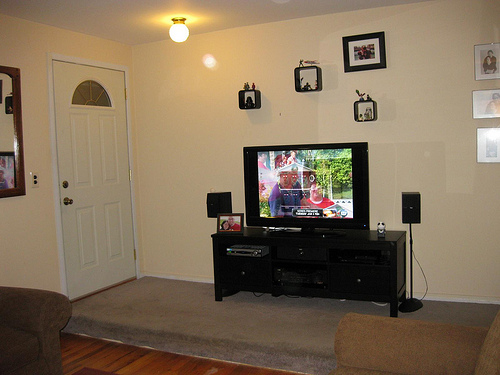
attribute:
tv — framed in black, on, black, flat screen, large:
[243, 143, 369, 234]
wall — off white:
[133, 1, 498, 303]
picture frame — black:
[340, 31, 387, 71]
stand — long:
[210, 231, 408, 317]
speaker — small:
[401, 191, 423, 312]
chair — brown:
[329, 313, 500, 373]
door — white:
[54, 61, 138, 300]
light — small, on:
[169, 16, 191, 44]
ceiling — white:
[1, 1, 414, 43]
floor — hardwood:
[60, 275, 497, 374]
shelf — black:
[239, 88, 261, 111]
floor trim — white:
[145, 273, 497, 305]